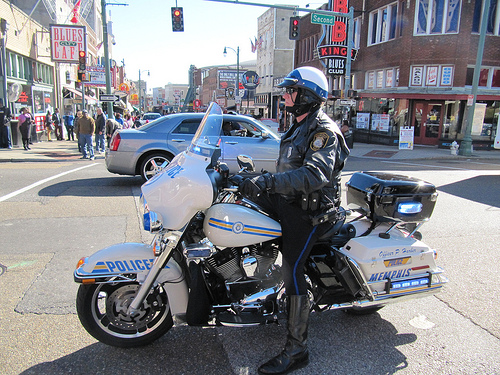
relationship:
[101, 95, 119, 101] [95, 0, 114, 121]
black/white sign on pole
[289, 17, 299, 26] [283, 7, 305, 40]
traffic signal on traffic light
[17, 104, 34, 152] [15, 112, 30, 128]
woman wearing shirt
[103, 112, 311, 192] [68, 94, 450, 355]
silver car beside motorcycle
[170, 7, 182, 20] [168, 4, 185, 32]
signal on light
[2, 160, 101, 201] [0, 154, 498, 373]
line on street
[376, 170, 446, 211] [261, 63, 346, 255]
box sitting on motorcycle